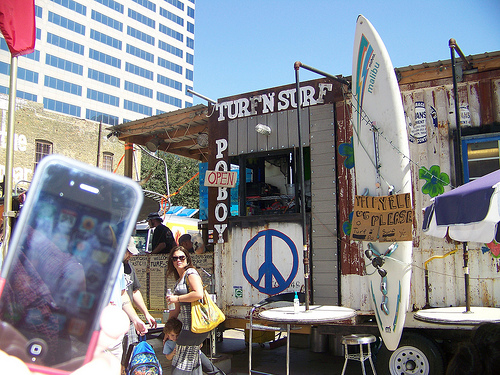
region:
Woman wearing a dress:
[167, 270, 209, 374]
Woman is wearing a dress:
[166, 267, 221, 372]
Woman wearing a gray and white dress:
[167, 268, 213, 373]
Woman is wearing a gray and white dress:
[165, 268, 210, 373]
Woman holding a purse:
[182, 266, 232, 336]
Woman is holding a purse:
[182, 268, 229, 337]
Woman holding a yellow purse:
[183, 267, 231, 334]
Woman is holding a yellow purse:
[183, 265, 229, 335]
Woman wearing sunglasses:
[167, 252, 188, 262]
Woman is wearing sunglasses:
[170, 250, 189, 262]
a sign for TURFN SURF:
[209, 79, 334, 120]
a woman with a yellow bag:
[187, 288, 224, 333]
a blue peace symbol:
[238, 226, 300, 293]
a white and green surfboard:
[347, 10, 417, 352]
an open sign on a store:
[203, 165, 237, 192]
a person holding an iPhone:
[0, 149, 145, 373]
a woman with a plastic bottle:
[163, 289, 176, 310]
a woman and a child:
[159, 244, 226, 374]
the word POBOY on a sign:
[208, 136, 228, 243]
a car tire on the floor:
[372, 333, 449, 374]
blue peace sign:
[233, 215, 313, 295]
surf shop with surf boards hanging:
[7, 0, 498, 360]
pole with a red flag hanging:
[0, 9, 36, 243]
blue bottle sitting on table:
[284, 268, 311, 321]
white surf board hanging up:
[348, 5, 434, 347]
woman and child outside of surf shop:
[127, 243, 238, 363]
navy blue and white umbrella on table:
[423, 168, 499, 330]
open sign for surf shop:
[196, 159, 293, 222]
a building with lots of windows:
[0, 0, 204, 134]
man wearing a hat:
[148, 189, 171, 293]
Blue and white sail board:
[355, 5, 412, 356]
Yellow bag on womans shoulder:
[184, 268, 227, 340]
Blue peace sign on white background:
[239, 227, 302, 293]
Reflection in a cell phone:
[1, 152, 140, 374]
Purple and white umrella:
[423, 158, 498, 250]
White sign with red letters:
[204, 169, 236, 187]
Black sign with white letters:
[212, 136, 227, 241]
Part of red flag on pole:
[1, 0, 38, 60]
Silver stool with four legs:
[340, 330, 376, 374]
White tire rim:
[387, 346, 431, 373]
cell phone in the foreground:
[0, 153, 143, 373]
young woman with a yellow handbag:
[162, 248, 223, 373]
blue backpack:
[127, 330, 160, 373]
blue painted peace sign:
[241, 229, 297, 291]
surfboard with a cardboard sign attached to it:
[346, 12, 416, 352]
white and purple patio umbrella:
[421, 164, 498, 245]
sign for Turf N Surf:
[213, 83, 331, 121]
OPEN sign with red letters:
[203, 165, 239, 189]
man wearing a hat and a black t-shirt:
[146, 212, 173, 254]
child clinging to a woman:
[160, 318, 185, 366]